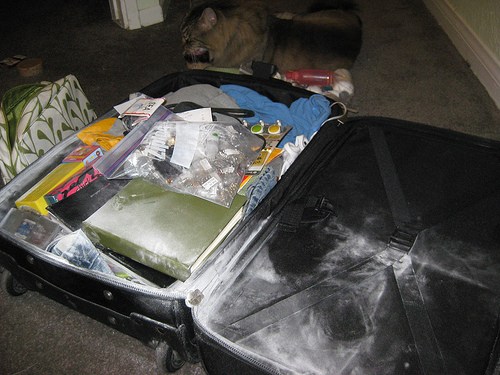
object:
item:
[285, 69, 334, 86]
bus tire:
[5, 277, 32, 296]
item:
[0, 205, 66, 255]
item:
[44, 165, 95, 202]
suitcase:
[1, 62, 500, 370]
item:
[92, 105, 264, 209]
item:
[79, 172, 247, 282]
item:
[267, 119, 284, 134]